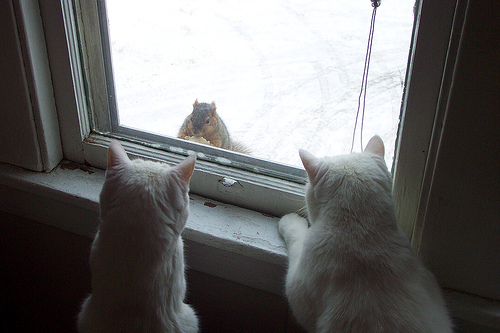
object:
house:
[4, 1, 498, 330]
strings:
[343, 3, 382, 150]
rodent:
[177, 98, 250, 155]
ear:
[297, 146, 333, 178]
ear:
[364, 133, 385, 159]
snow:
[115, 7, 360, 107]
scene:
[2, 0, 497, 331]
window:
[106, 0, 417, 178]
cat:
[277, 134, 454, 331]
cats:
[78, 139, 200, 331]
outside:
[113, 3, 432, 167]